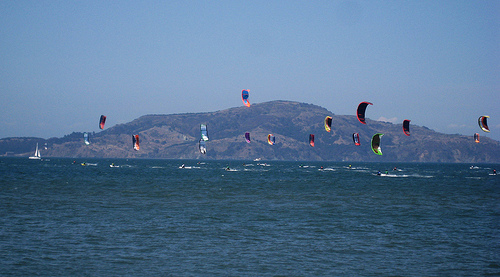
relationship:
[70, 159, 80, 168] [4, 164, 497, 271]
person in water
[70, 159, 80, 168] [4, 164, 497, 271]
person swimming in water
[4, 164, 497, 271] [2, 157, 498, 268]
water has surface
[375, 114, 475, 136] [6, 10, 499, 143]
cloud in sky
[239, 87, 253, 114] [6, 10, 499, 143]
kite in sky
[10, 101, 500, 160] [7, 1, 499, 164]
hill in background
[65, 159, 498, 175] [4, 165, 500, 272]
people on ocean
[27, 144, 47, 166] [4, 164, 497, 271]
boat on water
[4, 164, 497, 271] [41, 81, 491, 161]
water under kites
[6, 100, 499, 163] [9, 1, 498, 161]
land mass in distance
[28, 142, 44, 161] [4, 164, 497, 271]
sailboat in water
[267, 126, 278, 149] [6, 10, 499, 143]
kite in sky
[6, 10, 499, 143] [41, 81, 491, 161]
sky above kites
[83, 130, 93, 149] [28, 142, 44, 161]
kite close to sailboat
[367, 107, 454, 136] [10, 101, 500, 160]
cloud back of hill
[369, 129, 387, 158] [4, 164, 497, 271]
kite over water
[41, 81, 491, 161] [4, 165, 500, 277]
kites over ocean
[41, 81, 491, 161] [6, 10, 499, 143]
kites in sky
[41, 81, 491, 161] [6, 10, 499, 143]
kites flying in sky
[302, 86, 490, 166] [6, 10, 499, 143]
c-kites in sky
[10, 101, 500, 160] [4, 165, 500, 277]
hill front of ocean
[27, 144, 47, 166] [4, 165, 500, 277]
boat in ocean